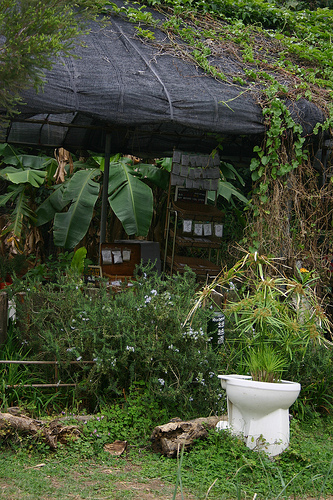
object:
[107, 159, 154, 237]
banana leaf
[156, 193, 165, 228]
leaves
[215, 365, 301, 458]
toilet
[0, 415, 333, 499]
ground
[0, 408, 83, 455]
log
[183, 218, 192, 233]
papers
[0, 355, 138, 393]
fence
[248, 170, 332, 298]
roots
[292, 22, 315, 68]
leaves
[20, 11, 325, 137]
roof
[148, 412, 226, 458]
log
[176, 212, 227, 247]
baskets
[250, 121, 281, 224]
vines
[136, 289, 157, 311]
flower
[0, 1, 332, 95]
plants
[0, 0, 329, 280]
umbrella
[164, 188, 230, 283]
shelves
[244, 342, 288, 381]
plant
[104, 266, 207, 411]
plants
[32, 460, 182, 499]
dirt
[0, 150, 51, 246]
tree leaves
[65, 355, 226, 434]
weeds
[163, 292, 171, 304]
flowers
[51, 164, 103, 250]
banana tree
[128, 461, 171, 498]
ground